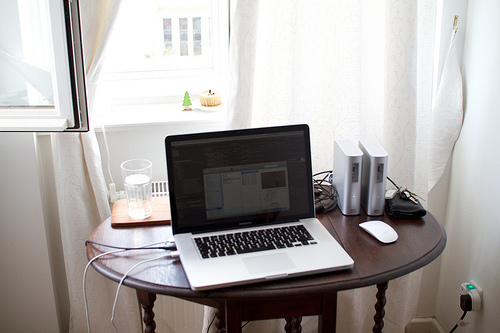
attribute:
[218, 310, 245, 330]
wooden leg — twisted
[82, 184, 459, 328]
wooden leg — twisted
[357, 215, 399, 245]
magic mouse — white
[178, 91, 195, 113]
christmas tree — small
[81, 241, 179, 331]
cord — black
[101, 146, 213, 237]
glass — clear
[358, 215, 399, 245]
mouse — white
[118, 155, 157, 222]
glass — tall, clear, filled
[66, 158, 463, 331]
table — round, wood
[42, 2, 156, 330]
curtain — white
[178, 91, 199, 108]
tree — small, green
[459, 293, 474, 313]
plug — black, large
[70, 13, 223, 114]
window — neighbors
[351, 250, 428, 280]
table — brown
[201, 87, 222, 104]
decoration — colorful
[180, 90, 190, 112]
decoration — colorful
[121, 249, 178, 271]
usb cord — white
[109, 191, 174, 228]
tray — wooden, brown, wood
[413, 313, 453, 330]
trim — white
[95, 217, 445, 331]
table — twisted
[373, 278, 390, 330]
leg — wooden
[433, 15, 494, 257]
wall — white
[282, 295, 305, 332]
leg — twisted, wooden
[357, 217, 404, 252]
mouse — white, flat, cordless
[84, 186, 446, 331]
wooden table — round, dark brown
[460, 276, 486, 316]
surge protector — white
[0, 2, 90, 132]
window frame — opened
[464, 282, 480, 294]
light — blue